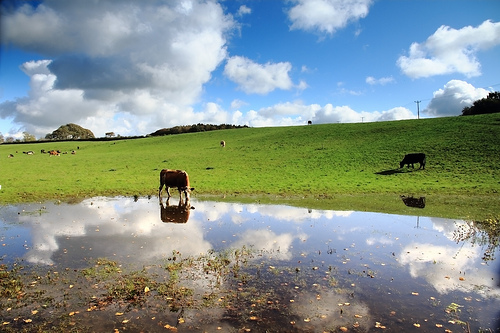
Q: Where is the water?
A: By the cow.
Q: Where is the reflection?
A: In the water.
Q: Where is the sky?
A: Above the hills.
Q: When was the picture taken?
A: Daytime.